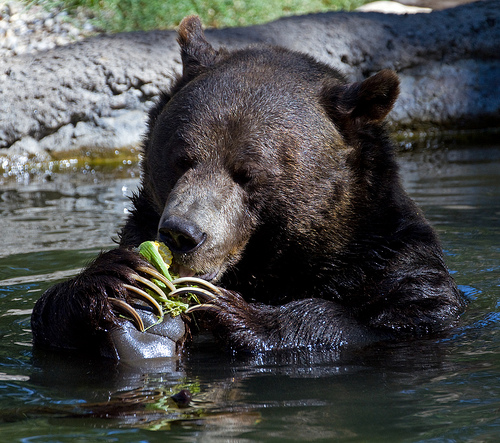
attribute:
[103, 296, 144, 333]
claw — long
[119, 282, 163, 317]
claw — long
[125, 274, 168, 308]
claw — long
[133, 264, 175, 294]
claw — long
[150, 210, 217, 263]
nose — big, black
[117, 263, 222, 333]
claws — brown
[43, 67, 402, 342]
bear — large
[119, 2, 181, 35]
plant — green, leafy, in back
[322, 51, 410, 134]
ear — big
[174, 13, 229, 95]
ear — big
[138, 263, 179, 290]
claw — long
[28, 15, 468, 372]
bear — eating, big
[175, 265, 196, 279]
tongue — bear's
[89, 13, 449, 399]
bear — brown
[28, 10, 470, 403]
fur — dark brown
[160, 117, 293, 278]
face — calm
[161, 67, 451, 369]
fur — wet